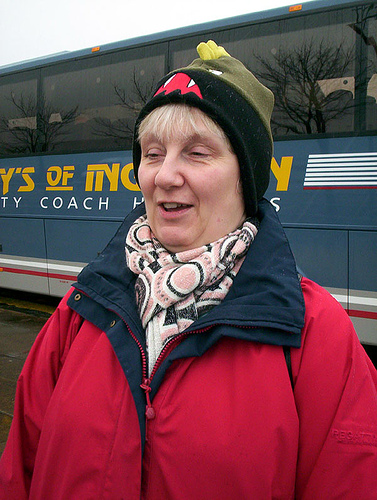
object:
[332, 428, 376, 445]
logo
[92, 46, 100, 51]
light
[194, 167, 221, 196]
cheek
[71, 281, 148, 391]
edge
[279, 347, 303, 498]
edge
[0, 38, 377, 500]
woman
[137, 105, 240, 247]
face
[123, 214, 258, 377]
scarf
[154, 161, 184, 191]
nose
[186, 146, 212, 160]
left eye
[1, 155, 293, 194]
company name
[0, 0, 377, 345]
bus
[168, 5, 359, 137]
window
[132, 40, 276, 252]
head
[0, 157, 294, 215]
company logo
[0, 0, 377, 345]
passenger bus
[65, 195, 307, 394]
collar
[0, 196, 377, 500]
coat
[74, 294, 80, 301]
snap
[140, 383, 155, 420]
pool string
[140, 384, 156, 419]
zipper handle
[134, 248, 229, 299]
neck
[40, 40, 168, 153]
window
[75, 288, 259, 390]
zipper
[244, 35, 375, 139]
tree reflection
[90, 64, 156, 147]
tree reflection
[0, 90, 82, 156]
tree reflection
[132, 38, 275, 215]
cap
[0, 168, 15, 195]
letters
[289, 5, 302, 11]
light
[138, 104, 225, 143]
hair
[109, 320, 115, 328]
button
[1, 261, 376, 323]
stripe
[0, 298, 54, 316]
line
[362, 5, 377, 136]
window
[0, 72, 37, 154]
window